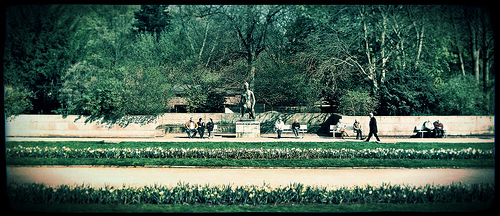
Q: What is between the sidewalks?
A: The grass field.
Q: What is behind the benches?
A: The wall.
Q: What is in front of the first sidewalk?
A: The flowers.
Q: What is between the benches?
A: The statue.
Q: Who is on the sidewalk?
A: The man.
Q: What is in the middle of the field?
A: The flowers.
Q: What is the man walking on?
A: The sidewalk.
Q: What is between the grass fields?
A: The pond.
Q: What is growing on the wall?
A: The vines.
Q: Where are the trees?
A: Lining the background.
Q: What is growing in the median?
A: Flowers.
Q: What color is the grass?
A: Green.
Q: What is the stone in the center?
A: A statue.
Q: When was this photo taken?
A: Daytime.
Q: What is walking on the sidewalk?
A: People.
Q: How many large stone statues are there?
A: One.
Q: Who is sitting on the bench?
A: People.